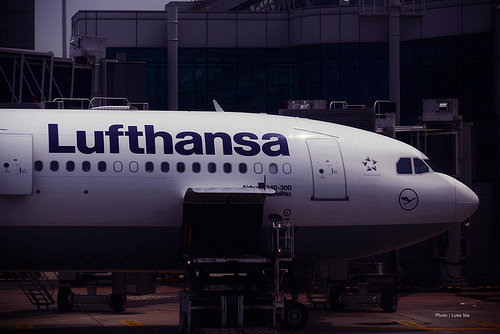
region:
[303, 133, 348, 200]
A door on the side of a plane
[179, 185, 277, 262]
Open hatch on the side of a plane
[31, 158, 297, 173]
Circular windows on a white plane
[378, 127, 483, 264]
Front end of a large plane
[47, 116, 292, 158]
Letters on the side of a plane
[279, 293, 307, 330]
Wheels underneath a plane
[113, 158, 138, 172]
Two closed windows on a plane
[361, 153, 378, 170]
Insignia on a plane's side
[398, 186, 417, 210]
Insignia on a plane's side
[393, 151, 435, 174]
Windows on the front of a plane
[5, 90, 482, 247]
large white airplane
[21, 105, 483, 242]
white airplane with blue letters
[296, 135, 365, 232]
door to a airplane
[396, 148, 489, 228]
nose of a airplane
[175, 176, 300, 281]
cargo hold door of a airplane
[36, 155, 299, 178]
many windows on a airplane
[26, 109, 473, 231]
blue and white airplane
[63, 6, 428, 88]
building behind a airplane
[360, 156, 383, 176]
symbol on a aircraft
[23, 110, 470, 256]
aircraft with many windows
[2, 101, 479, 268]
a large commercial airplane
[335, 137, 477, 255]
the nose of an airplane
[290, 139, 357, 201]
the door of an airplane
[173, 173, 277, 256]
the luggage compartment of an airplane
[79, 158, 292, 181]
the windows of an airplane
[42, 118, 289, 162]
the logo of an airplane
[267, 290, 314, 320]
the wheels of an airplane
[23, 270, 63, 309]
the stairs of an airplane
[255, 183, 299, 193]
the number of an airplane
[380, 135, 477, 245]
Cockpit and nose of an airplane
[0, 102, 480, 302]
Grounded Lufthansa commercial airplane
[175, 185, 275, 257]
Open luggage compartment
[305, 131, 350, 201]
Closed door on the side of a plane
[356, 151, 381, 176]
Circular Lufthansa logo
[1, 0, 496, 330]
Airplane hanger with a white plane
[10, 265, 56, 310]
Metal stairs on the opposite side of the plane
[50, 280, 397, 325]
Three sets of black wheels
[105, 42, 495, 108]
Large airport windows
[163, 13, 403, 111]
Two round white poles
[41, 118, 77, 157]
The letter is blue.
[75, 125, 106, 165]
The letter is blue.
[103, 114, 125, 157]
The letter is blue.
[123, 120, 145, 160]
The letter is blue.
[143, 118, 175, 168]
The letter is blue.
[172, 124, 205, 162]
The letter is blue.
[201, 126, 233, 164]
The letter is blue.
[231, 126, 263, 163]
The letter is blue.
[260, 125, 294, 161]
The letter is blue.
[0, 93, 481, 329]
The plane is blue and white.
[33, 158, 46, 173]
A window on a vehicle.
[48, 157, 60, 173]
A window on a vehicle.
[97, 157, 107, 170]
A window on a vehicle.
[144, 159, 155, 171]
A window on a vehicle.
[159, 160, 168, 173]
A window on a vehicle.